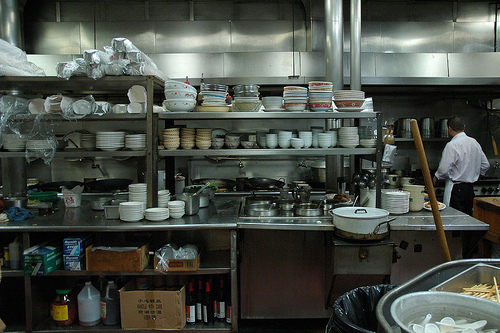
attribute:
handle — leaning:
[406, 114, 453, 265]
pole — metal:
[318, 0, 347, 85]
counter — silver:
[3, 196, 489, 232]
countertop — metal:
[1, 193, 493, 235]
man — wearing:
[437, 112, 489, 212]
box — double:
[57, 234, 84, 270]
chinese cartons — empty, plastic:
[39, 93, 73, 111]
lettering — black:
[135, 297, 165, 320]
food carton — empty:
[60, 185, 85, 207]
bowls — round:
[333, 87, 363, 107]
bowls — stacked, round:
[283, 84, 308, 108]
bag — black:
[315, 284, 382, 329]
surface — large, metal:
[3, 197, 240, 227]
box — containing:
[153, 244, 203, 272]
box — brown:
[95, 244, 129, 267]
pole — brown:
[403, 116, 453, 257]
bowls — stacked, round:
[162, 73, 199, 111]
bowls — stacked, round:
[308, 76, 334, 112]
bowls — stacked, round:
[331, 85, 366, 114]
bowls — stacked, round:
[232, 83, 262, 111]